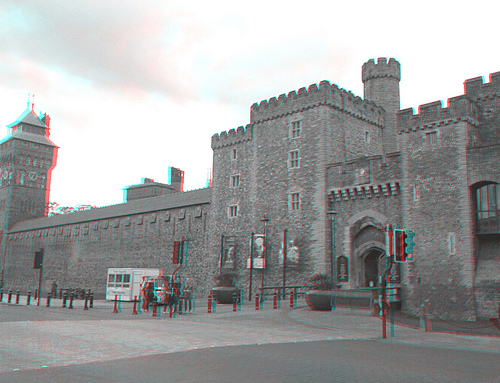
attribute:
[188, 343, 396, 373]
foreground — gray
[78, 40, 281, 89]
sky — cloudy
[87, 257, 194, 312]
truck — white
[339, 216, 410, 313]
door — open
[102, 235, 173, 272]
wall — red, black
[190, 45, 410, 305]
prison — old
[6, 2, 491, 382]
photo — 3D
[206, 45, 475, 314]
building — old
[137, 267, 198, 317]
people — walking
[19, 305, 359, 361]
walkway — brick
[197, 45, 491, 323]
castle — old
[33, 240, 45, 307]
post — black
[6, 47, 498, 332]
building — grey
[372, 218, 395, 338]
pole — black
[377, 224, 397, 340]
pole — red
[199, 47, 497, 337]
building — historical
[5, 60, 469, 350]
building — small, White